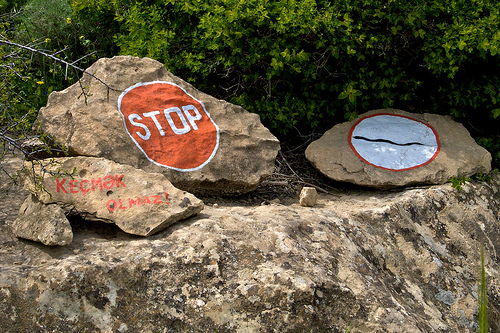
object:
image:
[353, 135, 424, 146]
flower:
[37, 81, 45, 84]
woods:
[0, 37, 111, 86]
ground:
[214, 202, 329, 216]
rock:
[304, 108, 492, 186]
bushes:
[420, 2, 498, 76]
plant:
[0, 33, 124, 106]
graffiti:
[54, 174, 169, 212]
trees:
[115, 0, 375, 75]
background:
[0, 0, 500, 125]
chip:
[300, 186, 320, 206]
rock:
[300, 187, 319, 207]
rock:
[24, 156, 205, 237]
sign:
[346, 113, 440, 172]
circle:
[347, 113, 441, 171]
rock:
[11, 193, 73, 245]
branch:
[1, 132, 29, 157]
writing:
[56, 174, 125, 195]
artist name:
[56, 174, 170, 213]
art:
[348, 113, 440, 170]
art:
[117, 81, 220, 172]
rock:
[32, 55, 281, 199]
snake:
[352, 136, 426, 147]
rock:
[21, 137, 47, 157]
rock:
[0, 180, 499, 331]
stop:
[126, 105, 203, 141]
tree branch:
[0, 39, 109, 90]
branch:
[234, 74, 242, 94]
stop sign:
[117, 81, 221, 172]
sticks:
[278, 150, 329, 193]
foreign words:
[55, 174, 123, 193]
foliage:
[351, 49, 356, 54]